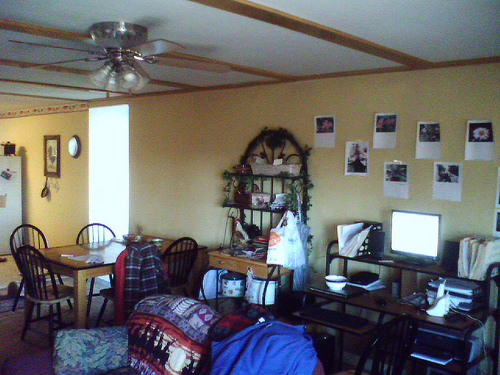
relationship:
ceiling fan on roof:
[7, 21, 232, 99] [1, 1, 491, 101]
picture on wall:
[468, 120, 493, 141] [124, 60, 498, 260]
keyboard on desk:
[306, 307, 368, 337] [301, 260, 485, 373]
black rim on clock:
[70, 133, 80, 158] [68, 135, 82, 158]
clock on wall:
[68, 135, 82, 158] [1, 57, 498, 266]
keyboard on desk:
[303, 307, 369, 330] [238, 198, 468, 366]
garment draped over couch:
[208, 320, 319, 371] [5, 290, 327, 370]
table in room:
[28, 232, 195, 284] [9, 4, 498, 364]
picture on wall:
[434, 161, 460, 185] [4, 53, 497, 293]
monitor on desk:
[390, 207, 442, 269] [328, 241, 471, 356]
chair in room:
[66, 270, 266, 372] [9, 4, 498, 364]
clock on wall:
[68, 135, 82, 158] [32, 91, 222, 231]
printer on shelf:
[412, 230, 479, 356] [399, 344, 498, 373]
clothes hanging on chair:
[122, 239, 172, 317] [98, 286, 113, 321]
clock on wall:
[65, 131, 83, 162] [136, 97, 210, 212]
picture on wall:
[373, 148, 405, 198] [138, 121, 218, 222]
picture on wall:
[42, 133, 62, 180] [1, 102, 86, 247]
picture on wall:
[414, 117, 447, 163] [124, 60, 498, 260]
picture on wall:
[316, 117, 333, 131] [137, 103, 209, 225]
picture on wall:
[375, 115, 398, 130] [137, 103, 209, 225]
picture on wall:
[418, 122, 440, 143] [137, 103, 209, 225]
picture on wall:
[468, 120, 493, 141] [137, 103, 209, 225]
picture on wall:
[434, 161, 460, 185] [137, 103, 209, 225]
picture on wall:
[427, 157, 466, 207] [125, 60, 499, 373]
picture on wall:
[42, 134, 62, 179] [2, 109, 92, 254]